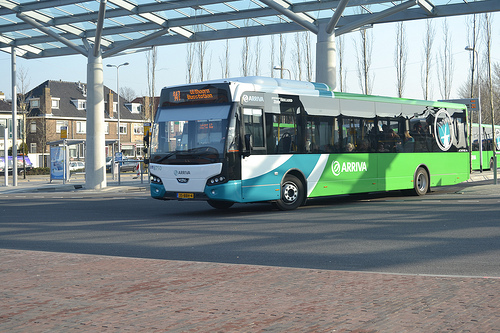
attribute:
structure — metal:
[84, 35, 112, 186]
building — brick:
[0, 78, 172, 175]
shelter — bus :
[0, 8, 484, 227]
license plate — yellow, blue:
[174, 190, 200, 200]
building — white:
[0, 86, 23, 183]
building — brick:
[24, 76, 149, 176]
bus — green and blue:
[152, 65, 482, 164]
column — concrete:
[82, 44, 107, 191]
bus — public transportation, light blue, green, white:
[137, 72, 478, 212]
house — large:
[15, 75, 127, 162]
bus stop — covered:
[46, 132, 126, 188]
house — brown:
[15, 75, 135, 169]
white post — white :
[0, 117, 18, 202]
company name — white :
[329, 152, 367, 182]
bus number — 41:
[160, 82, 182, 106]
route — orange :
[171, 92, 229, 105]